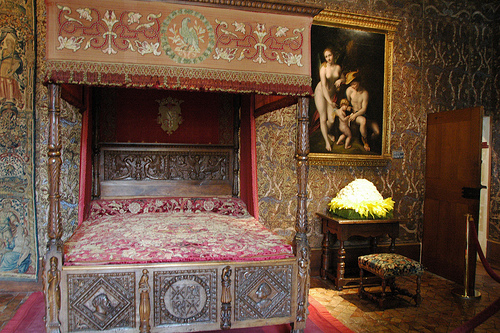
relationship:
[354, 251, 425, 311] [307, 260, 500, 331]
stool sitting on floor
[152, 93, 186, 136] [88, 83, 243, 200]
decoration on headboard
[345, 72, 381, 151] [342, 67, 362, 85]
person wearing a hat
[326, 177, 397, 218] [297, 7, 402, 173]
arrangement are under frame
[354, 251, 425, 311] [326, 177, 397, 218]
stool sitting near arrangement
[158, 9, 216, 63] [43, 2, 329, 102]
design on canopy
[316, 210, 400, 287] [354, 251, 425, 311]
table sitting by a stool